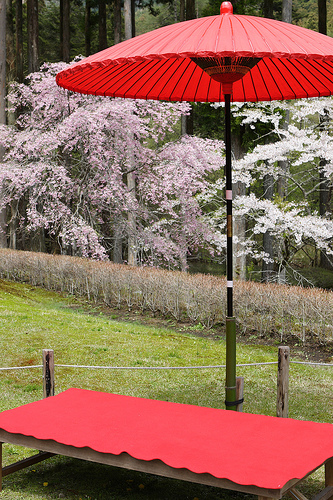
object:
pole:
[216, 84, 237, 411]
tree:
[0, 52, 225, 274]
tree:
[228, 94, 333, 285]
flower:
[139, 484, 145, 491]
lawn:
[0, 281, 333, 499]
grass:
[0, 274, 330, 500]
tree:
[51, 0, 83, 254]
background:
[0, 0, 333, 355]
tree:
[123, 1, 141, 268]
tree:
[25, 0, 50, 253]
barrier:
[0, 383, 333, 494]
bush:
[0, 245, 333, 348]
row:
[0, 247, 332, 348]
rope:
[1, 359, 331, 373]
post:
[276, 344, 294, 419]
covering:
[0, 385, 333, 493]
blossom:
[263, 230, 266, 234]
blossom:
[291, 160, 303, 167]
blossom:
[250, 126, 255, 130]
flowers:
[53, 232, 55, 234]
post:
[41, 350, 59, 394]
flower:
[259, 177, 263, 180]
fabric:
[54, 16, 332, 102]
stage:
[0, 383, 333, 500]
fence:
[0, 344, 332, 474]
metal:
[224, 93, 233, 320]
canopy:
[52, 1, 333, 108]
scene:
[3, 0, 332, 495]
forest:
[3, 2, 333, 299]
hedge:
[0, 245, 333, 348]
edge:
[0, 277, 333, 371]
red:
[0, 385, 332, 490]